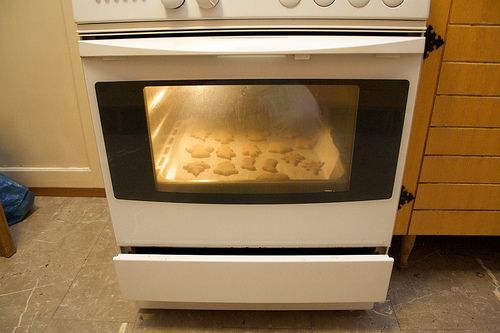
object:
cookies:
[178, 117, 328, 182]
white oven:
[75, 32, 430, 247]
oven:
[94, 77, 410, 205]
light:
[170, 81, 241, 101]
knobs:
[192, 0, 217, 10]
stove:
[69, 1, 439, 314]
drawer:
[111, 253, 395, 304]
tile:
[32, 193, 112, 330]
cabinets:
[393, 6, 497, 243]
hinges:
[421, 25, 448, 62]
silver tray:
[156, 130, 187, 189]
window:
[77, 26, 427, 132]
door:
[75, 28, 415, 61]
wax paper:
[321, 138, 343, 171]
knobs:
[159, 1, 409, 18]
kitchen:
[1, 0, 500, 333]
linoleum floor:
[1, 193, 500, 330]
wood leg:
[400, 234, 416, 269]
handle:
[77, 35, 428, 55]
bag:
[0, 165, 39, 219]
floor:
[31, 192, 114, 322]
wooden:
[4, 227, 6, 229]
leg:
[0, 203, 17, 259]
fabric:
[11, 193, 21, 206]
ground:
[3, 255, 107, 330]